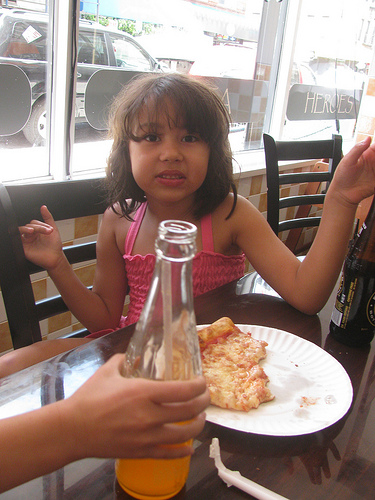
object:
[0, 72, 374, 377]
girl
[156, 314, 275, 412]
pizza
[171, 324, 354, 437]
plate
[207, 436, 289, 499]
wrapper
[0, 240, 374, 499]
table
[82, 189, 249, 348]
dress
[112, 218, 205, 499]
bottle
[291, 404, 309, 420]
grease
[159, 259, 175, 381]
straw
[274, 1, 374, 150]
window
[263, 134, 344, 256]
chair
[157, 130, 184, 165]
nose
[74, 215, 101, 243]
tile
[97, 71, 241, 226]
hair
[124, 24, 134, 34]
leaves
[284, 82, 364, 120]
sign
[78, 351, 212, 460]
hand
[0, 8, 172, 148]
car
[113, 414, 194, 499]
liquid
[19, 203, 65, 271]
hands